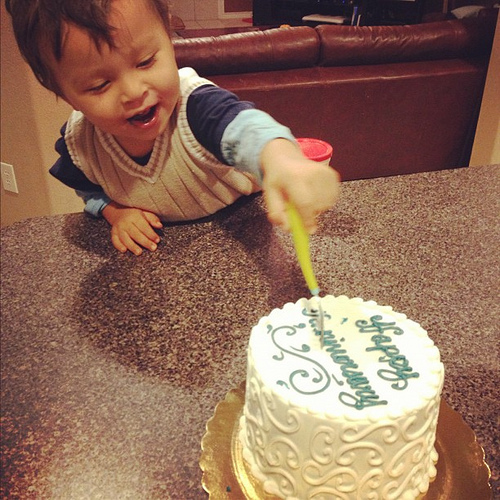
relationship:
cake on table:
[231, 293, 447, 500] [0, 159, 499, 498]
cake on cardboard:
[231, 293, 447, 500] [196, 375, 493, 498]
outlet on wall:
[2, 162, 19, 194] [1, 0, 95, 228]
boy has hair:
[4, 1, 341, 257] [8, 2, 176, 104]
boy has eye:
[4, 1, 341, 257] [135, 47, 158, 70]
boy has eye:
[4, 1, 341, 257] [82, 75, 111, 96]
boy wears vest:
[4, 1, 341, 257] [64, 68, 259, 221]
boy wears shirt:
[4, 1, 341, 257] [66, 64, 305, 217]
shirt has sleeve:
[66, 64, 305, 217] [190, 84, 301, 183]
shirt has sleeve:
[66, 64, 305, 217] [55, 135, 119, 221]